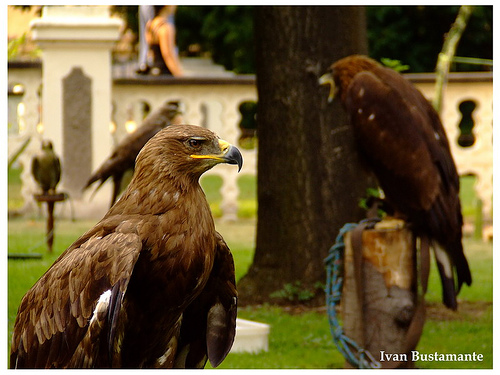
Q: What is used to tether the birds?
A: A blue cord hanging over post.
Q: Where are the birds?
A: On perches.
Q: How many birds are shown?
A: 4.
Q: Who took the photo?
A: Ivan Bustamante.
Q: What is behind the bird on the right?
A: Tree.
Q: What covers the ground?
A: Grass.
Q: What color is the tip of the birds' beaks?
A: Black.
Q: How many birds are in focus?
A: 1.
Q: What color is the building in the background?
A: White.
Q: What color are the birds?
A: Brown.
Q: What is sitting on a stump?
A: Bird.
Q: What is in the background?
A: Tree trunk.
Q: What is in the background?
A: Wall.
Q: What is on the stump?
A: Blue rope.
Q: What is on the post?
A: Bird.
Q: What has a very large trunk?
A: Tree.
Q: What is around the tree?
A: Grass.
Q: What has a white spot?
A: The bird.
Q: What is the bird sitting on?
A: A tree trunk.